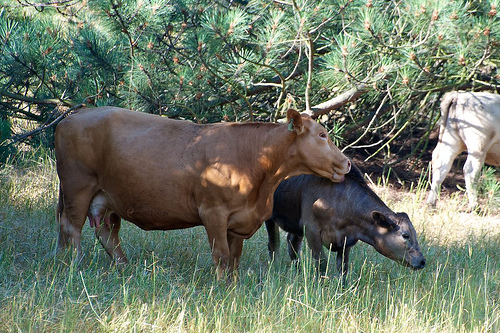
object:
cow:
[55, 105, 351, 286]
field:
[1, 154, 496, 333]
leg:
[199, 199, 233, 284]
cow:
[421, 89, 498, 215]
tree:
[0, 0, 500, 164]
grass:
[1, 146, 500, 333]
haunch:
[228, 184, 277, 239]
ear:
[286, 108, 302, 125]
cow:
[262, 158, 425, 291]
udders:
[88, 190, 115, 232]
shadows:
[1, 184, 497, 332]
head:
[288, 109, 353, 183]